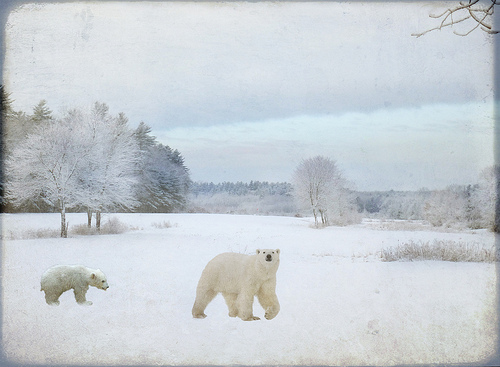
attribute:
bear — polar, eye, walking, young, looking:
[189, 220, 326, 333]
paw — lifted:
[250, 288, 311, 322]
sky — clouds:
[197, 54, 319, 127]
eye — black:
[253, 236, 270, 259]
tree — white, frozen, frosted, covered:
[27, 109, 143, 230]